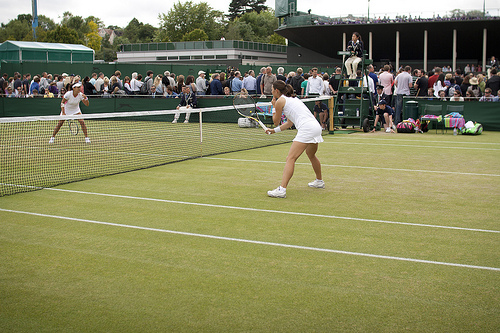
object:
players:
[48, 80, 325, 198]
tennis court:
[0, 117, 497, 333]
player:
[48, 83, 92, 144]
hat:
[72, 82, 83, 88]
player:
[263, 80, 325, 198]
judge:
[344, 33, 362, 80]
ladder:
[333, 50, 381, 129]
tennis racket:
[232, 92, 272, 135]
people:
[0, 56, 499, 134]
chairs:
[420, 104, 464, 135]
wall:
[0, 98, 499, 131]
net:
[0, 96, 333, 197]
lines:
[1, 128, 500, 272]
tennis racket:
[67, 120, 79, 136]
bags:
[238, 118, 259, 128]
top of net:
[0, 95, 333, 125]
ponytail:
[281, 84, 297, 98]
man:
[171, 85, 199, 124]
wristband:
[274, 126, 282, 133]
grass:
[4, 117, 500, 330]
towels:
[421, 111, 474, 129]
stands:
[0, 56, 500, 124]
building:
[0, 40, 95, 64]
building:
[116, 40, 286, 65]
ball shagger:
[369, 100, 396, 134]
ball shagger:
[313, 98, 329, 131]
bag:
[462, 121, 483, 136]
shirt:
[63, 90, 85, 109]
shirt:
[278, 94, 317, 129]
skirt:
[292, 121, 325, 144]